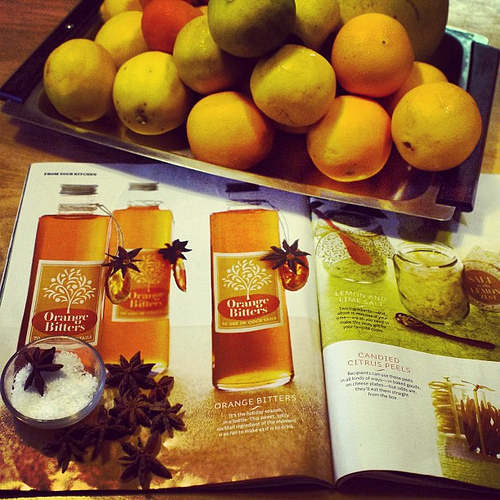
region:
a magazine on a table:
[4, 98, 496, 497]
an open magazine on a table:
[12, 98, 479, 498]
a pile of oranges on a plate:
[23, 2, 496, 252]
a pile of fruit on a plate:
[32, 3, 490, 217]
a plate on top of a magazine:
[19, 15, 492, 461]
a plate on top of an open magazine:
[8, 12, 499, 494]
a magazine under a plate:
[12, 5, 488, 484]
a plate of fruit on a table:
[1, 15, 494, 290]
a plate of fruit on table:
[3, 4, 498, 458]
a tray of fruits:
[52, 0, 487, 181]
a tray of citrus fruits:
[35, 6, 450, 211]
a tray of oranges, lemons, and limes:
[15, 0, 457, 210]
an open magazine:
[27, 165, 492, 495]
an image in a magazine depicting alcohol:
[37, 172, 312, 467]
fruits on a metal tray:
[1, 5, 453, 186]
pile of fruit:
[30, 0, 487, 205]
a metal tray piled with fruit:
[1, 5, 439, 201]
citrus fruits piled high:
[0, 0, 433, 206]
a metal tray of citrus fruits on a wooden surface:
[0, 3, 448, 218]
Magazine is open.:
[33, 190, 437, 435]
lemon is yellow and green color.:
[111, 7, 471, 155]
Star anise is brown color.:
[104, 345, 201, 461]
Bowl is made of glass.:
[9, 333, 118, 438]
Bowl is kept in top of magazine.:
[1, 335, 145, 433]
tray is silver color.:
[101, 124, 328, 217]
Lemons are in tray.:
[140, 102, 341, 217]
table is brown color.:
[3, 139, 55, 188]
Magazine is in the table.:
[6, 39, 134, 257]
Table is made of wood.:
[5, 13, 53, 50]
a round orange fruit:
[182, 87, 267, 163]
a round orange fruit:
[113, 50, 190, 137]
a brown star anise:
[155, 235, 186, 261]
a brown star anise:
[265, 238, 306, 273]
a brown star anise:
[100, 243, 142, 278]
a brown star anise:
[20, 345, 62, 395]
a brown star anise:
[106, 353, 152, 395]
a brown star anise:
[148, 399, 183, 434]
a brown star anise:
[120, 435, 167, 487]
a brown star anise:
[81, 406, 128, 461]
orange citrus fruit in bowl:
[392, 93, 479, 170]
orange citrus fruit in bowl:
[311, 108, 379, 182]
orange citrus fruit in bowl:
[258, 65, 324, 122]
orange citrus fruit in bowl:
[191, 107, 266, 152]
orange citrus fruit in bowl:
[222, 14, 289, 82]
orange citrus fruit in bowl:
[171, 35, 218, 92]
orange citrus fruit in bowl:
[114, 74, 182, 146]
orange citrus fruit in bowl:
[41, 53, 98, 115]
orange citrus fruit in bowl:
[336, 20, 412, 72]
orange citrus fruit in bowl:
[167, 20, 214, 68]